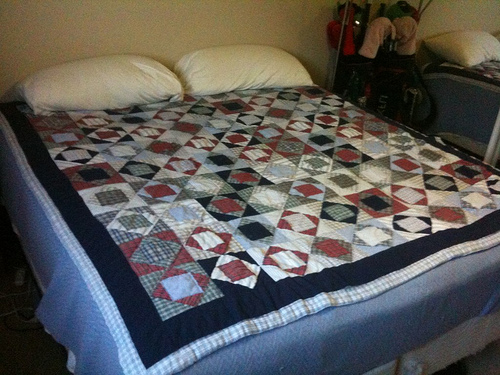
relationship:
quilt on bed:
[183, 111, 444, 265] [25, 91, 469, 369]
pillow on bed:
[422, 27, 499, 67] [0, 85, 500, 374]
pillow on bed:
[171, 43, 316, 98] [421, 53, 499, 147]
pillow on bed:
[11, 54, 185, 119] [421, 53, 499, 147]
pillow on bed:
[19, 49, 182, 113] [1, 42, 499, 373]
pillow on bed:
[171, 42, 316, 100] [1, 42, 499, 373]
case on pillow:
[13, 52, 185, 118] [11, 54, 185, 119]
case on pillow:
[68, 69, 171, 109] [170, 29, 311, 104]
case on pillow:
[204, 51, 315, 85] [16, 24, 186, 133]